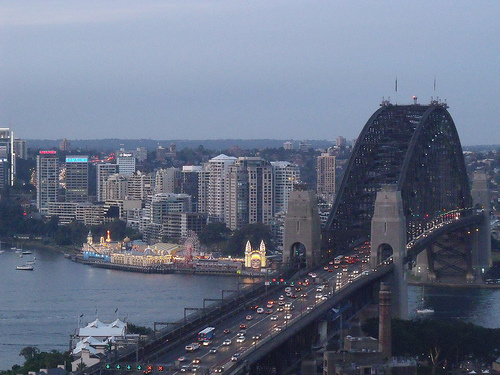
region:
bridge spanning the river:
[48, 103, 477, 373]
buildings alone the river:
[3, 126, 498, 256]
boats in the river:
[7, 240, 42, 280]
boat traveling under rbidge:
[416, 303, 437, 320]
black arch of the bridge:
[333, 97, 476, 233]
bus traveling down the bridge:
[198, 325, 215, 342]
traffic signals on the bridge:
[60, 334, 162, 374]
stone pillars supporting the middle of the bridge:
[272, 180, 424, 345]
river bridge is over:
[10, 257, 499, 360]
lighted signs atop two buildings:
[37, 146, 89, 161]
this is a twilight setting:
[15, 8, 497, 295]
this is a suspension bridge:
[345, 95, 485, 212]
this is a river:
[42, 245, 212, 332]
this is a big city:
[27, 140, 337, 235]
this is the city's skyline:
[38, 149, 340, 263]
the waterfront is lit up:
[97, 238, 276, 296]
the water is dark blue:
[47, 267, 144, 330]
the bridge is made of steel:
[344, 114, 426, 179]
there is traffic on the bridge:
[213, 285, 358, 367]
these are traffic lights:
[93, 354, 168, 371]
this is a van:
[280, 298, 295, 314]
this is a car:
[222, 336, 234, 348]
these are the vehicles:
[215, 274, 337, 354]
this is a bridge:
[68, 75, 498, 370]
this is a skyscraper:
[201, 130, 309, 255]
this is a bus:
[191, 325, 223, 347]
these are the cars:
[243, 274, 312, 349]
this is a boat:
[9, 255, 35, 275]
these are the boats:
[0, 233, 36, 283]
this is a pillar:
[347, 163, 429, 321]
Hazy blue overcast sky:
[126, 54, 233, 99]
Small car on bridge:
[207, 347, 220, 354]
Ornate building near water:
[242, 238, 269, 270]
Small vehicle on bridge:
[245, 313, 255, 320]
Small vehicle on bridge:
[270, 312, 279, 324]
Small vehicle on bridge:
[300, 291, 307, 300]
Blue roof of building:
[61, 154, 91, 167]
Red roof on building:
[36, 149, 59, 157]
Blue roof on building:
[211, 149, 233, 165]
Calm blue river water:
[35, 290, 80, 310]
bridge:
[337, 80, 467, 240]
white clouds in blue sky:
[17, 45, 47, 70]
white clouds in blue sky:
[129, 17, 164, 57]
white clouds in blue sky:
[194, 37, 236, 99]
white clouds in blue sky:
[16, 55, 64, 93]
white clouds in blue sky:
[337, 41, 369, 72]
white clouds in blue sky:
[383, 36, 424, 68]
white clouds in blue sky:
[39, 43, 92, 133]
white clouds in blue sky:
[86, 45, 146, 127]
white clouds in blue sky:
[179, 10, 229, 44]